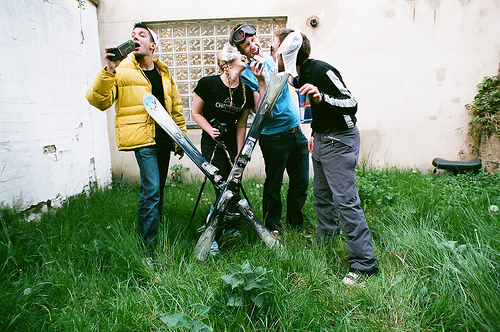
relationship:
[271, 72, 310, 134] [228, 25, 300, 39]
man with goggles